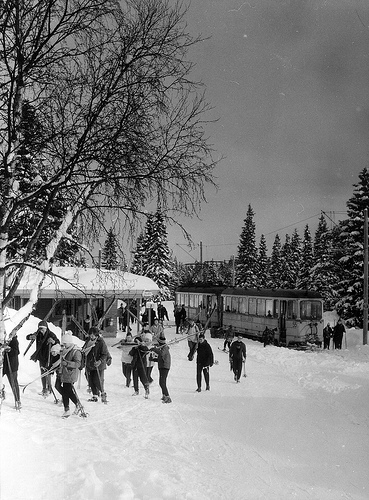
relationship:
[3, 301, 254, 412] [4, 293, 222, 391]
people carrying skis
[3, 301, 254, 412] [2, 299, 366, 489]
people walking in snow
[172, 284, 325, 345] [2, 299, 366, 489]
train in snow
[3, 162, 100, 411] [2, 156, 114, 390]
snow on branches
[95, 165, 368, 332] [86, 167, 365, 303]
snow on trees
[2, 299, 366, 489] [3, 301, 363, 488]
snow on ground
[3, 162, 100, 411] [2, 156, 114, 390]
snow sticking to branches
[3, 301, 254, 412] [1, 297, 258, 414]
people lining up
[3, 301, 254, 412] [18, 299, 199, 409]
people carrying equipment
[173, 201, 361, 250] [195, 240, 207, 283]
cables supported by pole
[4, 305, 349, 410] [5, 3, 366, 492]
bundled for weather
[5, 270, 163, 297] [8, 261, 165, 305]
snow on roof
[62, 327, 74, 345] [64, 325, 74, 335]
hat with pom pom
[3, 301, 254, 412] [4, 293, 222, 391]
people with skis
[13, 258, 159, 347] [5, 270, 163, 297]
house with snow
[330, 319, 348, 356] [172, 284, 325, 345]
person standing by train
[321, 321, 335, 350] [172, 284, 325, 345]
person standing by train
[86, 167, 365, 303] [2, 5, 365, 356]
trees in background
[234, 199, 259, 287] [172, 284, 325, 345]
tree behind train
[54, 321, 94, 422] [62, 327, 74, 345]
lady with hat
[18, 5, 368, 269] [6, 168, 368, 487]
sky above everything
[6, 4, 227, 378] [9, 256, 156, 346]
tree next to building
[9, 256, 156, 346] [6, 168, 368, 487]
building next to everything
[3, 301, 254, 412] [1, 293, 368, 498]
people walking up hill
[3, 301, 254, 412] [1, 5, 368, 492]
people walking to ski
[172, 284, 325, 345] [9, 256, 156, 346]
train next to building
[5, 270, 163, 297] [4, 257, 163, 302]
snow on top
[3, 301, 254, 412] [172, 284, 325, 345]
people standing next to train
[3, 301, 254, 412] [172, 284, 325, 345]
people next to train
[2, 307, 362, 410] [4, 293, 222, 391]
skiers got skis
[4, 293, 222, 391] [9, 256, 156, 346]
skis at building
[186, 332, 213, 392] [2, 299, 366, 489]
man walking in snow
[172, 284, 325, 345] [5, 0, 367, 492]
train in image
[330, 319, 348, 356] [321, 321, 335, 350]
person near person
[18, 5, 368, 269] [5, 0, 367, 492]
sky in image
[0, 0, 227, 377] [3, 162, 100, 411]
tree covered in snow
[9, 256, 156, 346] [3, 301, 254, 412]
building behind people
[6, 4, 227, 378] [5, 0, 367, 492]
tree in image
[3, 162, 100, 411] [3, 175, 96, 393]
snow on trunk